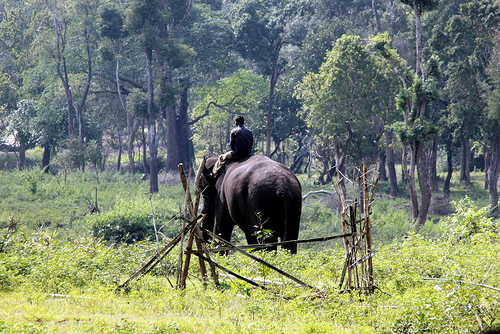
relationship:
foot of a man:
[206, 172, 216, 179] [205, 116, 252, 179]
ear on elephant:
[176, 150, 210, 189] [138, 150, 353, 262]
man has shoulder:
[205, 116, 252, 179] [243, 127, 251, 137]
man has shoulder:
[205, 116, 252, 179] [230, 125, 237, 135]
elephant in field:
[194, 147, 306, 258] [1, 165, 498, 332]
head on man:
[233, 114, 248, 123] [212, 109, 261, 171]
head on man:
[233, 114, 245, 126] [205, 112, 255, 179]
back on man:
[236, 136, 248, 142] [221, 110, 266, 234]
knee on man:
[215, 152, 227, 164] [205, 112, 255, 179]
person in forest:
[207, 114, 258, 185] [4, 2, 493, 219]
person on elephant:
[204, 114, 254, 176] [181, 149, 308, 264]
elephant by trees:
[185, 147, 307, 255] [398, 0, 476, 235]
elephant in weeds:
[193, 153, 303, 251] [0, 165, 499, 331]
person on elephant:
[210, 115, 254, 177] [193, 153, 303, 251]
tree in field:
[300, 37, 394, 215] [1, 165, 498, 332]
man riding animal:
[227, 115, 257, 158] [193, 148, 301, 247]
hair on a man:
[233, 113, 243, 124] [205, 116, 252, 179]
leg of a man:
[206, 150, 236, 184] [210, 116, 253, 179]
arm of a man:
[190, 147, 302, 262] [205, 112, 255, 179]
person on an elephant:
[210, 115, 254, 177] [193, 153, 303, 251]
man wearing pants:
[210, 116, 253, 179] [209, 151, 229, 175]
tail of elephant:
[276, 186, 289, 245] [193, 153, 303, 251]